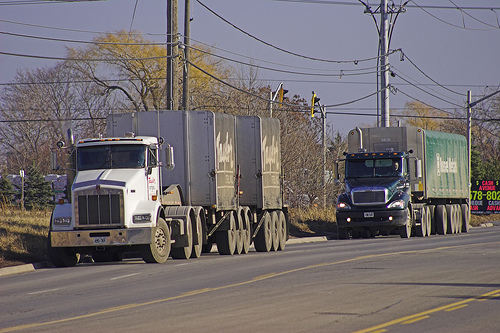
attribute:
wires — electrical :
[397, 49, 471, 94]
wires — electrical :
[201, 3, 377, 64]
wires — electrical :
[191, 75, 378, 115]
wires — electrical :
[5, 27, 159, 55]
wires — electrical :
[1, 76, 168, 87]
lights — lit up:
[387, 197, 404, 207]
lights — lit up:
[335, 201, 350, 210]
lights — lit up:
[130, 210, 152, 224]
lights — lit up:
[50, 214, 71, 225]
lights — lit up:
[346, 148, 398, 158]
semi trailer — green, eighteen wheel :
[335, 124, 472, 237]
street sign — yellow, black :
[268, 84, 292, 121]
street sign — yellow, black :
[300, 87, 327, 126]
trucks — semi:
[24, 60, 499, 306]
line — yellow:
[360, 297, 470, 331]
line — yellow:
[51, 295, 166, 323]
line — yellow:
[445, 304, 467, 314]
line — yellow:
[481, 294, 498, 301]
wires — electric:
[185, 72, 496, 132]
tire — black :
[147, 218, 174, 268]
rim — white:
[152, 224, 168, 254]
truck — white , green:
[333, 119, 485, 246]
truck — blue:
[330, 109, 496, 266]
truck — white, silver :
[43, 106, 292, 256]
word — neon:
[480, 178, 494, 184]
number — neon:
[471, 189, 477, 201]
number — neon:
[475, 187, 483, 201]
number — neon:
[485, 190, 490, 198]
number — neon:
[490, 187, 496, 201]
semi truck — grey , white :
[42, 101, 289, 259]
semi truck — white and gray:
[40, 104, 295, 269]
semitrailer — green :
[329, 119, 483, 233]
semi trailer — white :
[49, 106, 287, 263]